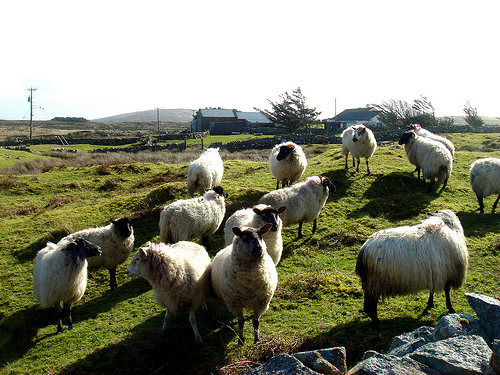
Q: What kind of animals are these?
A: Sheep.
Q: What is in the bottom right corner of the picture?
A: Rocks.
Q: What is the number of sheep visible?
A: Fourteen.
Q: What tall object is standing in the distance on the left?
A: Telephone pole.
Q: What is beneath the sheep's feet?
A: Grass.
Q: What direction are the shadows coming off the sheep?
A: Left.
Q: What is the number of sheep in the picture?
A: 14.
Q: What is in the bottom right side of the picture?
A: Small rock wall.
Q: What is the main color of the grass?
A: Green.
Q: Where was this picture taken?
A: In a field.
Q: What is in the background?
A: Buildings.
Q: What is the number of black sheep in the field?
A: 0.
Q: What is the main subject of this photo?
A: Sheep.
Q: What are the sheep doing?
A: Standing.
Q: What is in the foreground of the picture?
A: Rocks.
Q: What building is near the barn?
A: House.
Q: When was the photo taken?
A: Daytime.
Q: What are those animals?
A: Sheep.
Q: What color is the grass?
A: Green.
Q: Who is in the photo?
A: Nobody.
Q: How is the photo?
A: Clear.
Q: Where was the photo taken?
A: In a pasture.